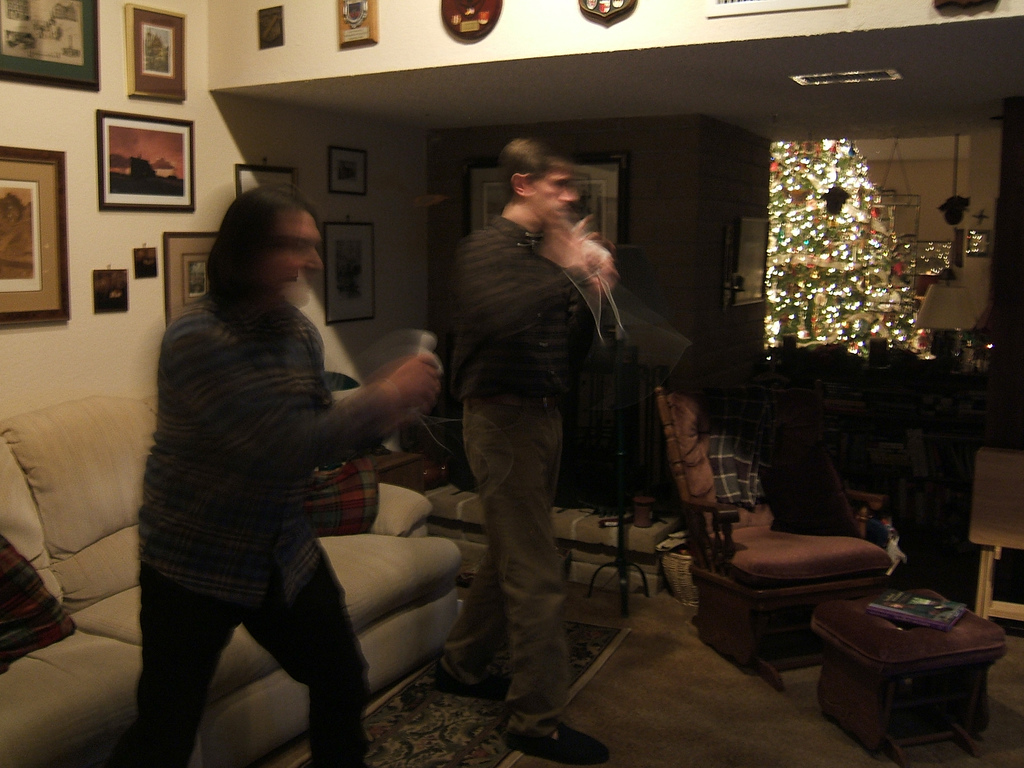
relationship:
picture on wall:
[9, 142, 83, 339] [2, 12, 147, 410]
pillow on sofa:
[2, 524, 91, 680] [2, 293, 467, 751]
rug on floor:
[575, 620, 794, 765] [434, 628, 921, 765]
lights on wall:
[769, 136, 944, 359] [728, 58, 984, 404]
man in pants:
[431, 126, 676, 732] [442, 374, 631, 703]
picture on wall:
[92, 104, 201, 217] [2, 1, 437, 427]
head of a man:
[198, 178, 328, 336] [118, 180, 443, 762]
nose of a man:
[304, 242, 330, 275] [118, 180, 443, 762]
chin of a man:
[267, 275, 320, 314] [106, 166, 456, 746]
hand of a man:
[371, 350, 449, 428] [106, 166, 456, 746]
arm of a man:
[164, 338, 389, 481] [118, 180, 443, 762]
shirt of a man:
[132, 296, 398, 608] [118, 180, 443, 762]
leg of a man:
[118, 565, 242, 764] [106, 166, 456, 746]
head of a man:
[198, 178, 328, 336] [106, 166, 456, 746]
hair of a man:
[196, 182, 317, 347] [106, 166, 456, 746]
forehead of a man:
[274, 201, 329, 247] [106, 166, 456, 746]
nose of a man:
[300, 243, 329, 276] [118, 180, 443, 762]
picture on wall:
[3, 121, 83, 357] [37, 83, 70, 151]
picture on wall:
[91, 104, 200, 217] [54, 126, 96, 179]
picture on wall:
[91, 104, 200, 217] [76, 210, 115, 237]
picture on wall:
[18, 22, 206, 133] [37, 98, 92, 151]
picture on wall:
[137, 223, 192, 316] [37, 331, 128, 394]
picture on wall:
[307, 124, 370, 204] [57, 335, 94, 377]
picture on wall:
[323, 206, 408, 330] [31, 336, 96, 382]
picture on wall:
[210, 145, 316, 198] [46, 305, 92, 390]